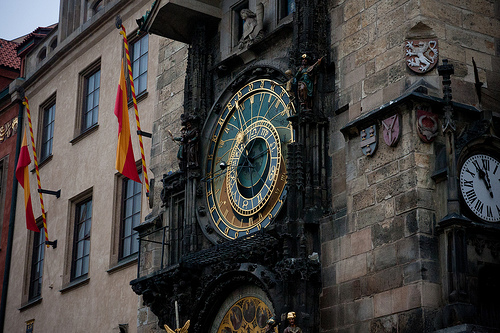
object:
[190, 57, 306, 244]
clock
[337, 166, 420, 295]
wall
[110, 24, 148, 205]
flag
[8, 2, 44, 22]
sky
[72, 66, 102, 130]
window